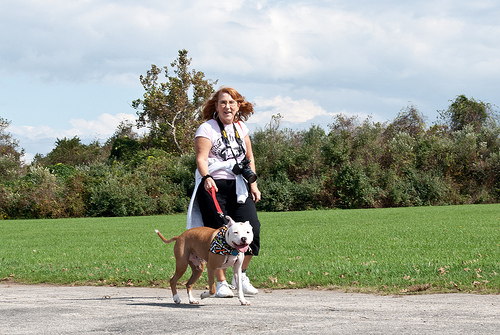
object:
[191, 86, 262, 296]
woman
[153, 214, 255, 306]
pitt bull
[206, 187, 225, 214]
pink leash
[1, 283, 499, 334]
pathway